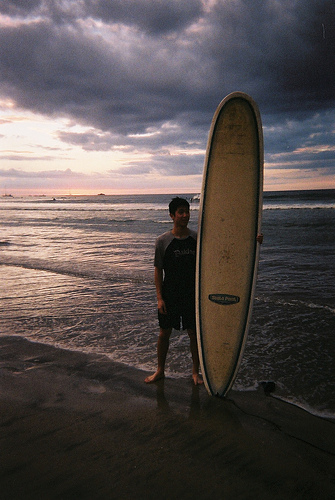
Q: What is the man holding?
A: A surfboard.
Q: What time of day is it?
A: The evening.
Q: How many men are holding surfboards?
A: 1.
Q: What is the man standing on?
A: The sand.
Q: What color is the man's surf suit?
A: Black and gray.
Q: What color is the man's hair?
A: Black.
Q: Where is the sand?
A: On the ground.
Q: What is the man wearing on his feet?
A: Nothing.